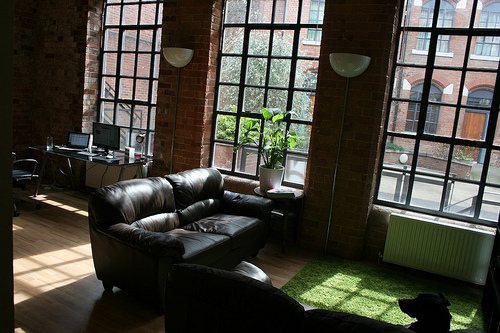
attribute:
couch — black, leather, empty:
[91, 152, 272, 268]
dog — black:
[397, 285, 456, 327]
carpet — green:
[321, 265, 418, 327]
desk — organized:
[38, 141, 144, 171]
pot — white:
[258, 165, 280, 194]